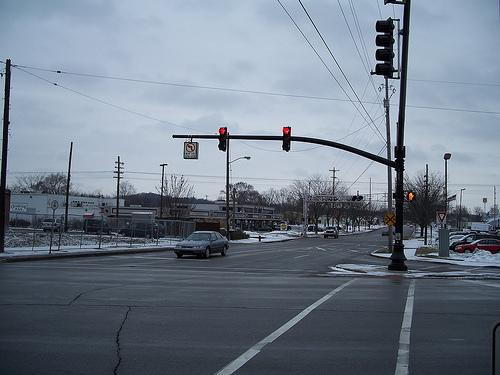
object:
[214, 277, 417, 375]
markings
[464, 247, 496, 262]
pile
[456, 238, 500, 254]
car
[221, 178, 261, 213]
tree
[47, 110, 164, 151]
cloud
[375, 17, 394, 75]
lights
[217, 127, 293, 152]
lights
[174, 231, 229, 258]
car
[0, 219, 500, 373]
road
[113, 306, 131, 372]
crack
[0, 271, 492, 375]
pavement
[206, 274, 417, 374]
paint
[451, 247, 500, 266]
snow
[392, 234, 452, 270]
curb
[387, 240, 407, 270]
base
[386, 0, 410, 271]
pole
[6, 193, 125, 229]
building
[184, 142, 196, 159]
sign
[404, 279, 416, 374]
stripe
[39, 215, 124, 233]
people